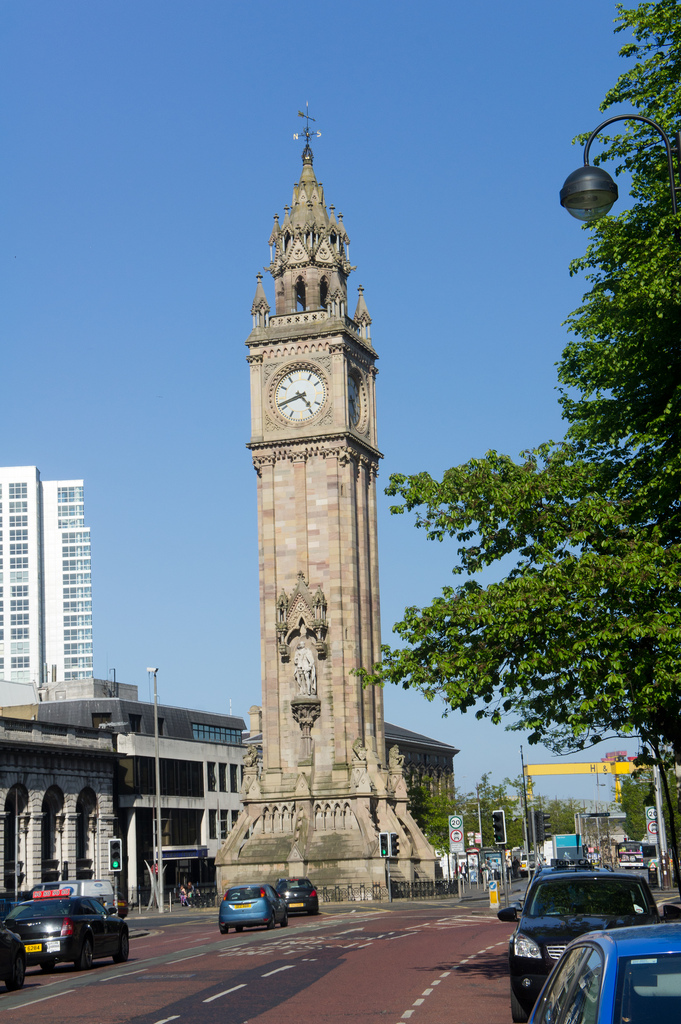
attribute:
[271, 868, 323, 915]
car — dark blue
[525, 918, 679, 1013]
car — sky blue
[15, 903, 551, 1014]
road — red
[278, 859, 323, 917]
car — small and black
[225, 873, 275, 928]
car — small and blue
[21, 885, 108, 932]
car — black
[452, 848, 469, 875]
pole — gray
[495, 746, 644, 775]
sign — yellow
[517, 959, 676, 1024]
car — blue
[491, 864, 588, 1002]
vehicle — black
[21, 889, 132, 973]
car — one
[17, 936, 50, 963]
plate — yellow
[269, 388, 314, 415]
hands — clock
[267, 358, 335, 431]
clock — black, white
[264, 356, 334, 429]
clock — white, large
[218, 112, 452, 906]
clocktower — large, stone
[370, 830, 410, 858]
lights — traffic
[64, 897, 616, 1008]
street — multi-lane, city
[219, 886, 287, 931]
car — blue, small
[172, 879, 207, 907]
people — some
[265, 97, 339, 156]
weathervane — one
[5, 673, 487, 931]
buildings — some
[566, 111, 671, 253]
pole — black, light, street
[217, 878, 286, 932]
car — blue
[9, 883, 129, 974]
car — black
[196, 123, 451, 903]
tower — tall, clock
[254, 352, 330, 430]
clock — round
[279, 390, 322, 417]
hands — clock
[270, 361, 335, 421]
clock — one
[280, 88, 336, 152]
vane — weather, metal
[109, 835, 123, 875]
light — street, green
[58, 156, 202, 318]
sky — blue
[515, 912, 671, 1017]
car — blue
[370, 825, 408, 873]
stoplight — one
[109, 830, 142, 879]
stoplight — one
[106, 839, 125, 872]
light — green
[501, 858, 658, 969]
truck — one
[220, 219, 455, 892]
tower — one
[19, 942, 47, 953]
license plate — yellow, black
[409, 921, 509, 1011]
line — white, dotted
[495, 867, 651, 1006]
suv — black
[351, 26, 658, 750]
leaves — dark green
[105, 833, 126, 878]
traffic light — shining green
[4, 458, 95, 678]
building — tall, white